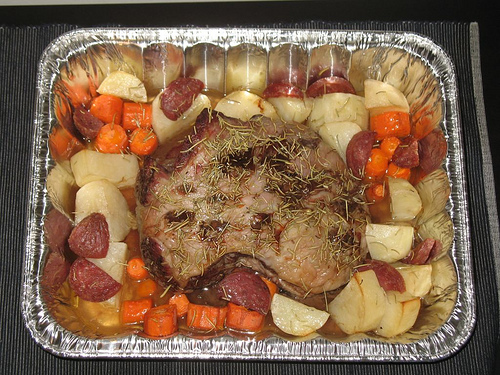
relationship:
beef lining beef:
[134, 107, 372, 298] [134, 107, 372, 298]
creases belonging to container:
[41, 330, 468, 363] [19, 27, 476, 362]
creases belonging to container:
[19, 32, 59, 349] [19, 27, 476, 362]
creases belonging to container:
[46, 24, 446, 57] [19, 27, 476, 362]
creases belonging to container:
[442, 46, 479, 338] [19, 27, 476, 362]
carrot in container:
[370, 106, 417, 141] [19, 27, 476, 362]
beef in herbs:
[134, 107, 372, 298] [146, 107, 375, 281]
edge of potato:
[398, 295, 420, 305] [323, 270, 385, 338]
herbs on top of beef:
[180, 118, 361, 249] [133, 106, 373, 297]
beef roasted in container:
[165, 135, 357, 288] [19, 27, 476, 362]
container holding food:
[19, 27, 476, 362] [51, 39, 449, 338]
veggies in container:
[96, 70, 153, 105] [19, 27, 476, 362]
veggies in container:
[150, 84, 211, 139] [19, 27, 476, 362]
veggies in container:
[211, 90, 277, 122] [19, 27, 476, 362]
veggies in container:
[266, 89, 316, 126] [19, 27, 476, 362]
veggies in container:
[122, 99, 153, 132] [19, 27, 476, 362]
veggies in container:
[95, 120, 126, 155] [19, 27, 476, 362]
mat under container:
[0, 13, 62, 119] [19, 27, 476, 362]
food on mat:
[68, 70, 436, 337] [0, 21, 500, 375]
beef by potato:
[134, 107, 372, 298] [270, 293, 331, 337]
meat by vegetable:
[219, 266, 271, 313] [228, 302, 265, 337]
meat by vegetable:
[62, 256, 122, 301] [145, 302, 178, 339]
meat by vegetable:
[62, 212, 110, 255] [363, 77, 410, 114]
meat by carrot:
[160, 74, 201, 120] [370, 111, 411, 141]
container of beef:
[19, 27, 476, 362] [134, 107, 372, 298]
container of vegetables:
[19, 27, 476, 362] [75, 228, 165, 325]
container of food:
[19, 27, 476, 362] [52, 70, 437, 334]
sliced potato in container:
[53, 153, 142, 188] [19, 27, 476, 362]